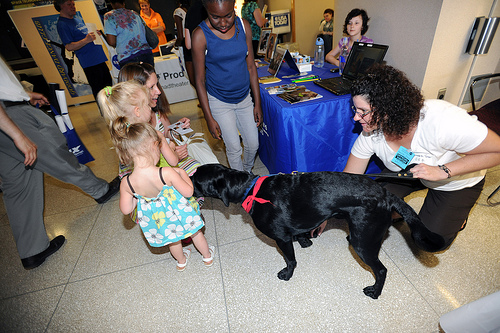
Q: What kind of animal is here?
A: Dog.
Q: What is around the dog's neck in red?
A: Bandana.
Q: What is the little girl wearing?
A: Dress.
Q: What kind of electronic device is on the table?
A: Laptop.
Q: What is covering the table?
A: Tablecloth.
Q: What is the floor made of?
A: Tile.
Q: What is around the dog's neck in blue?
A: Collar.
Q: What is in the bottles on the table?
A: Water.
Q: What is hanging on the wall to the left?
A: Poster.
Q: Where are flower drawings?
A: On little girl's dress.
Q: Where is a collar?
A: Around dog's neck.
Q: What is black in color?
A: Dog.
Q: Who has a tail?
A: The dog.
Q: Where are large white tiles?
A: On the floor.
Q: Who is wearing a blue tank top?
A: Woman standing.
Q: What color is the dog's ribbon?
A: Red.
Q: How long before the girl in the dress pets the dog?
A: Right now.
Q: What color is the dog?
A: Black.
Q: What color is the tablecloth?
A: Blue.